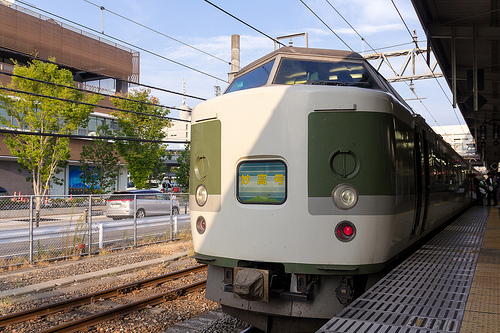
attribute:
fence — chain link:
[2, 192, 191, 267]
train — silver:
[191, 46, 483, 318]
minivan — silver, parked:
[106, 189, 179, 217]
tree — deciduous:
[4, 52, 102, 226]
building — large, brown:
[3, 3, 141, 203]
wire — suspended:
[392, 0, 466, 139]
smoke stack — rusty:
[227, 34, 241, 84]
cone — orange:
[12, 191, 17, 202]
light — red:
[342, 224, 354, 234]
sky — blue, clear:
[5, 0, 466, 125]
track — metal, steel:
[1, 263, 207, 329]